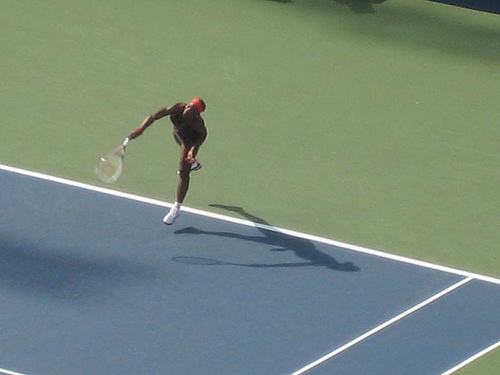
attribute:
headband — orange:
[188, 94, 203, 119]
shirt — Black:
[173, 119, 194, 136]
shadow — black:
[173, 199, 359, 274]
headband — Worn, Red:
[190, 97, 205, 114]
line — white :
[371, 296, 427, 343]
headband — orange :
[192, 98, 208, 113]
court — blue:
[3, 2, 499, 373]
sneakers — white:
[159, 207, 183, 224]